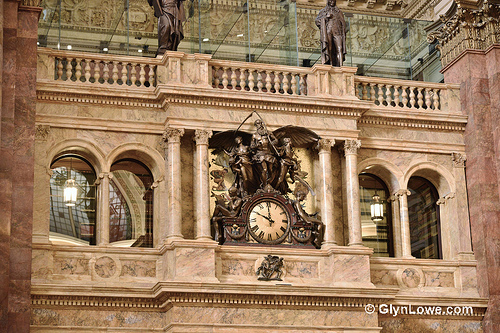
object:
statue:
[145, 0, 186, 59]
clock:
[206, 118, 323, 251]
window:
[104, 148, 156, 250]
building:
[0, 1, 498, 332]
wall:
[28, 49, 483, 331]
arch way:
[46, 150, 105, 250]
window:
[354, 162, 403, 259]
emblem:
[254, 252, 286, 282]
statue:
[311, 0, 348, 68]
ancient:
[101, 141, 166, 249]